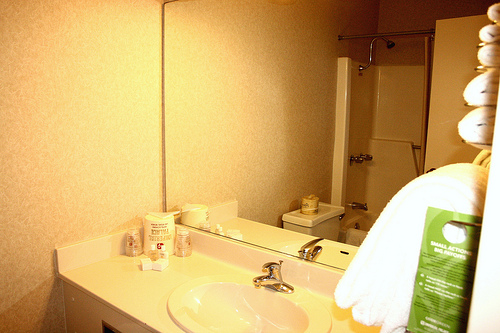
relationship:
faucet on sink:
[251, 253, 302, 303] [166, 260, 329, 331]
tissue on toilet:
[295, 185, 323, 218] [281, 202, 347, 233]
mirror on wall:
[162, 0, 499, 279] [162, 0, 477, 331]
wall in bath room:
[162, 0, 477, 331] [0, 4, 495, 330]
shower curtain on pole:
[422, 26, 434, 178] [335, 29, 432, 42]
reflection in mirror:
[164, 19, 495, 246] [168, 7, 480, 244]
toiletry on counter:
[171, 228, 196, 252] [53, 219, 362, 331]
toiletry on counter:
[142, 242, 171, 268] [53, 219, 362, 331]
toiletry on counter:
[144, 208, 171, 250] [53, 219, 362, 331]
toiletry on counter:
[123, 218, 144, 253] [53, 219, 362, 331]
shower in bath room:
[334, 25, 423, 248] [0, 0, 467, 331]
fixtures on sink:
[250, 260, 296, 295] [56, 217, 376, 332]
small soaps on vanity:
[142, 250, 168, 272] [52, 214, 387, 331]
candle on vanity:
[123, 212, 199, 292] [54, 225, 342, 331]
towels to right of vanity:
[263, 141, 497, 316] [54, 223, 412, 330]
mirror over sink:
[162, 0, 499, 279] [148, 240, 340, 332]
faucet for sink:
[253, 258, 297, 296] [165, 276, 332, 331]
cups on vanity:
[150, 213, 200, 255] [54, 223, 412, 330]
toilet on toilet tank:
[281, 201, 347, 241] [283, 202, 343, 245]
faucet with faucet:
[253, 258, 297, 296] [253, 258, 297, 296]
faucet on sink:
[253, 258, 297, 296] [164, 256, 334, 332]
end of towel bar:
[410, 143, 421, 152] [412, 140, 423, 151]